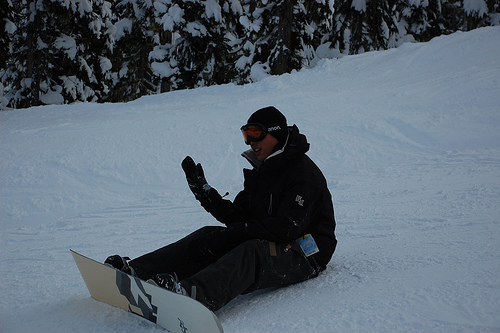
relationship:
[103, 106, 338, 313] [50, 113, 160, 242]
guy sitting on snow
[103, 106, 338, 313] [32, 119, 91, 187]
guy on snow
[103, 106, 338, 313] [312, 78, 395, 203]
guy on snow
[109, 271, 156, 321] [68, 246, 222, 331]
design on snowboard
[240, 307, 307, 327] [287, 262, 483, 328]
snow on ground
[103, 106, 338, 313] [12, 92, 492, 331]
guy on ground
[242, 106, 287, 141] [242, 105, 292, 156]
hat on head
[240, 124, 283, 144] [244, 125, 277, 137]
goggles has lens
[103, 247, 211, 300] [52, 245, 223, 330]
boots on snowboard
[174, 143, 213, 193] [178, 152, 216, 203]
hand has mitten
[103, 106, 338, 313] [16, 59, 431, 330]
guy was snowboarding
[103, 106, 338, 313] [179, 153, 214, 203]
guy wearing gloves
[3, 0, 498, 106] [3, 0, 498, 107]
snow on top of branches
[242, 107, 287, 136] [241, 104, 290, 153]
hat on top of head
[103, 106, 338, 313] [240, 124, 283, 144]
guy wearing goggles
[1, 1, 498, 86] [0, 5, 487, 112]
snow on tree limbs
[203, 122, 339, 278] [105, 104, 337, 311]
coat on body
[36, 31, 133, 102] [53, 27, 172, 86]
snow on bush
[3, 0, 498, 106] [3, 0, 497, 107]
snow on trees